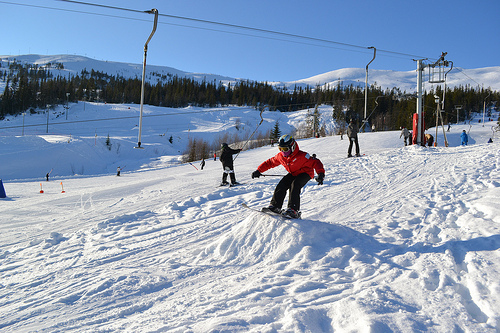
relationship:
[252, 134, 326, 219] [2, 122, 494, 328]
man at park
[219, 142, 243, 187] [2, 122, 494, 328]
person at park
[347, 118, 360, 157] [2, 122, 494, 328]
man at park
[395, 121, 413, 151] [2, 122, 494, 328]
person at park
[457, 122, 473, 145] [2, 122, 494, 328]
person at park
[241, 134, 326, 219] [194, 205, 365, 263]
snowboarder on ramp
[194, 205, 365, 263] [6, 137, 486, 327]
ramp made of snow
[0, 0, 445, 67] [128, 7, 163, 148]
wire with poles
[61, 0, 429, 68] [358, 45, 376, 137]
wire with poles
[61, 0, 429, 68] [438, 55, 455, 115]
wire with poles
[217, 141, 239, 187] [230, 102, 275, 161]
person hanging onto pole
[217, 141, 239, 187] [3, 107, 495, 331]
person being moved on snow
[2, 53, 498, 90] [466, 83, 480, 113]
mountain behind tree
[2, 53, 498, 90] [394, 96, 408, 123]
mountain behind tree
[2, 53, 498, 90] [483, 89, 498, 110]
mountain behind tree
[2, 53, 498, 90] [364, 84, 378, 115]
mountain behind tree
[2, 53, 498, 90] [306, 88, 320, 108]
mountain behind tree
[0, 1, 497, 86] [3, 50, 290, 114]
sky behind mountain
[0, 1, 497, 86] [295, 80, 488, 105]
sky behind mountain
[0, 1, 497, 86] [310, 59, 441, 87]
sky behind mountain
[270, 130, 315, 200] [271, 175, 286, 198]
snowboarder with knee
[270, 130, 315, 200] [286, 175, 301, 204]
snowboarder with knee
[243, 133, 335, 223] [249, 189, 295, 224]
man on skis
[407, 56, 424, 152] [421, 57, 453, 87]
pole holding up lift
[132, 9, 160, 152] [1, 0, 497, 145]
part of ski lift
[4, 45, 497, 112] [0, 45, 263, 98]
range of mountain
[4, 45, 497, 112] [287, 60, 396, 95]
range of mountain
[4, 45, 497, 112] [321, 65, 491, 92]
range of mountain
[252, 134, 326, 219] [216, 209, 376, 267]
man skiing up mound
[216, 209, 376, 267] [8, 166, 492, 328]
mound of snow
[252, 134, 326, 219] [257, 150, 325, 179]
man wearing jacket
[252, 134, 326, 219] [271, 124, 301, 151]
man wearing helmet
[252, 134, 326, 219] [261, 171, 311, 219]
man wearing pants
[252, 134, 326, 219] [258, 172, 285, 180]
man has pole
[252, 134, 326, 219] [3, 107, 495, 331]
man skiing in snow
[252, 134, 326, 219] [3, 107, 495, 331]
man skiing over snow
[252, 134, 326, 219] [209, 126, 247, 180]
man wearing jacket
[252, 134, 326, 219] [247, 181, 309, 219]
man wearing skis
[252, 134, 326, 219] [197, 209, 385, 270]
man skiing up mound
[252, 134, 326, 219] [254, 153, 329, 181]
man wearing jacket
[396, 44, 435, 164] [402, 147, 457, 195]
metal post in snow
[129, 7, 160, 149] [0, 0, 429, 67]
pole hanging from wire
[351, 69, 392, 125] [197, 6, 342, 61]
pole on wire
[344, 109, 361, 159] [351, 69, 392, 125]
man hanging pole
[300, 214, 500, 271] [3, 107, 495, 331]
shadow on snow